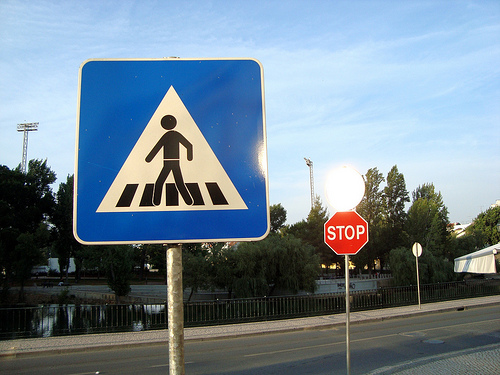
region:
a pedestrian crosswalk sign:
[70, 55, 270, 241]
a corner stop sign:
[320, 210, 365, 255]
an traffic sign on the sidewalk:
[410, 240, 420, 305]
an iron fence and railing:
[185, 287, 341, 322]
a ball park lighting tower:
[15, 118, 39, 174]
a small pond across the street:
[1, 295, 168, 334]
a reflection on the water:
[28, 301, 163, 333]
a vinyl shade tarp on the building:
[453, 243, 498, 274]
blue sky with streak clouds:
[263, 0, 498, 153]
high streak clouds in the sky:
[265, 30, 496, 151]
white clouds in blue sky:
[4, 8, 44, 55]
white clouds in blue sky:
[18, 58, 58, 95]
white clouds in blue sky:
[109, 4, 201, 41]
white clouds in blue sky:
[283, 34, 304, 87]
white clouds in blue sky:
[290, 100, 325, 132]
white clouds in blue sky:
[334, 15, 394, 94]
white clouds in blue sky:
[383, 57, 430, 117]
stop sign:
[315, 205, 373, 250]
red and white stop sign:
[312, 205, 370, 261]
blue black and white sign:
[75, 58, 285, 255]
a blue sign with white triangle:
[69, 47, 285, 246]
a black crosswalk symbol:
[116, 114, 223, 206]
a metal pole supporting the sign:
[161, 249, 196, 371]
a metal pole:
[341, 261, 356, 368]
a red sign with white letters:
[320, 210, 379, 253]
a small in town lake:
[26, 297, 264, 315]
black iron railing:
[298, 288, 448, 309]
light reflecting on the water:
[38, 305, 69, 334]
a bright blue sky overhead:
[16, 10, 483, 129]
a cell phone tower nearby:
[295, 157, 320, 212]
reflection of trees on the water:
[0, 294, 165, 335]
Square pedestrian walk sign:
[70, 57, 267, 244]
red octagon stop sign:
[322, 210, 369, 256]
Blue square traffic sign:
[75, 56, 270, 245]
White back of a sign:
[412, 241, 424, 257]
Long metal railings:
[0, 279, 498, 341]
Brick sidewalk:
[359, 339, 498, 373]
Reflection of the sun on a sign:
[253, 135, 269, 178]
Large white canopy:
[450, 240, 498, 277]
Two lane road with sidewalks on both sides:
[1, 295, 498, 374]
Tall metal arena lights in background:
[15, 118, 45, 169]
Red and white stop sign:
[321, 208, 369, 256]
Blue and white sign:
[70, 53, 265, 247]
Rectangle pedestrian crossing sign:
[70, 55, 268, 245]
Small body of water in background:
[6, 303, 87, 336]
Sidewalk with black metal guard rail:
[5, 305, 120, 351]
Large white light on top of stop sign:
[324, 161, 365, 214]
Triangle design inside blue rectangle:
[70, 57, 262, 242]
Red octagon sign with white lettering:
[320, 214, 368, 255]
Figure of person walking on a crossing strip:
[95, 83, 246, 215]